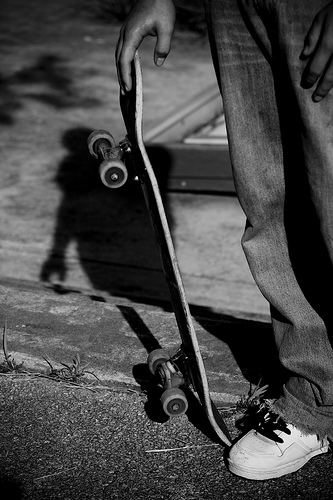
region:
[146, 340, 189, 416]
wheels on the back of a skateboard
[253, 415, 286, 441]
black shoelaces on a white shoe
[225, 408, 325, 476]
white shoes with black laces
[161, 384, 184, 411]
skateboard wheel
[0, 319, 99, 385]
small plants that have grown from the ground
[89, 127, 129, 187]
front wheels on a skateboard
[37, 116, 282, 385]
shadows on the ground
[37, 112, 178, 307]
a persons shadow on the ground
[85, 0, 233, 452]
skateboard in a persons hand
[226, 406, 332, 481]
a shoe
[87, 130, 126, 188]
wheels on a skateboard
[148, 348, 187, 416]
wheels on a skateboard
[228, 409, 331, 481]
a man's skateboard shoe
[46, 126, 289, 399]
shadow of a man with a skateboard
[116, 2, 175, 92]
a man's hand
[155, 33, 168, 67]
a man's thumb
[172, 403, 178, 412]
bolt for skateboard wheel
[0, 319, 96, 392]
grass growing in cracks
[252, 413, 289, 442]
a man's black shoelaces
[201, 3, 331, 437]
a man's pant leg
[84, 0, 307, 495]
man holding a skateboard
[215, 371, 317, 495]
man's shoes are white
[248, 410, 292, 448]
the shoelaces are black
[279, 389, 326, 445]
jeans torn on bottom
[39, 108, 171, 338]
shadow of man on ground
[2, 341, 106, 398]
grass between the concrete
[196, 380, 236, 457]
the skateboard is black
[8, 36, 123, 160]
shadow of tree on ground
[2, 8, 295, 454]
ground is made of concrete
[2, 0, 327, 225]
top half of man's body cropped out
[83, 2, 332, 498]
A kid holding his skate board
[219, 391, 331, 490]
White sneakers with black laces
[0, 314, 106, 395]
Grass growing through the concrete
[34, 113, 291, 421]
Shadow of a boy and his skateboard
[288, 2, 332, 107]
Boy's hand rested at his side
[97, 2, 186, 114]
Fingertips holding up a skateboard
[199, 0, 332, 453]
Jeans with no hem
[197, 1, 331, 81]
Bleached lines in fabric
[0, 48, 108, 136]
Shadow of a tree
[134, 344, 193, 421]
Wheels on a skateboard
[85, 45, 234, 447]
An older skateboard held vertically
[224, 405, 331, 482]
A younger kid's tennis shoe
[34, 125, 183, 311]
A shadow of someone standing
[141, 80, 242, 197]
Wooden railing on ground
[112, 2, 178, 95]
A child's hand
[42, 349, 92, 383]
Grass growing next to cement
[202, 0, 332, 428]
Jeans worn by a child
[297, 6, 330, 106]
A child's hand resting by his side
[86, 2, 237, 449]
A hand holding a skateboard